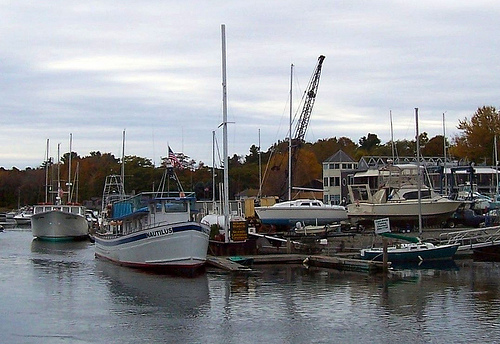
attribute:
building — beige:
[321, 143, 358, 206]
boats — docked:
[37, 178, 224, 322]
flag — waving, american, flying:
[144, 141, 200, 179]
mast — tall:
[201, 16, 249, 187]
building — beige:
[233, 184, 288, 218]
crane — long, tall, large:
[288, 52, 337, 139]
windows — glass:
[27, 202, 96, 226]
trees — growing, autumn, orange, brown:
[74, 159, 179, 193]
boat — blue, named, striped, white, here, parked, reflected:
[32, 229, 83, 250]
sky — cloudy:
[48, 41, 179, 127]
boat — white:
[134, 219, 235, 258]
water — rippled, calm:
[49, 275, 234, 329]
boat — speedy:
[367, 223, 499, 279]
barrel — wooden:
[234, 220, 262, 249]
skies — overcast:
[222, 16, 451, 73]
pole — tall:
[171, 14, 289, 248]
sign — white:
[364, 218, 401, 236]